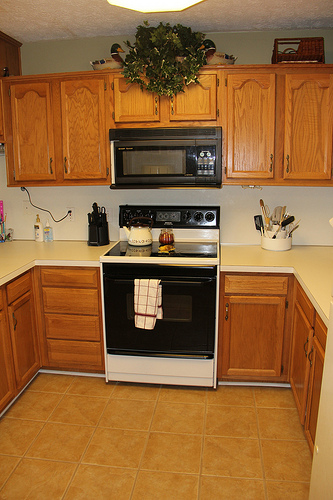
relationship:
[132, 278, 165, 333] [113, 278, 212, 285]
towel on handle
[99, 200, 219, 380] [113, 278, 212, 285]
stove has handle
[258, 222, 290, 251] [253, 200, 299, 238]
holder holds utensils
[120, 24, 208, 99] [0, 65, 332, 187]
plant on cabinet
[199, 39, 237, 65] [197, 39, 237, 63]
statue of duck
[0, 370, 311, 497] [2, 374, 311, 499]
tile on floor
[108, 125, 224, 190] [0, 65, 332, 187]
microwave on cabinet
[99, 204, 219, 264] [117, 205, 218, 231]
stove has panel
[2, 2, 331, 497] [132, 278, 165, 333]
kitchen has towel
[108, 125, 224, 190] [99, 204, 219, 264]
microwave over stove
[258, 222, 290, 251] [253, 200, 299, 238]
holder has utensils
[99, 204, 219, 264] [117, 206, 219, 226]
stove has knobs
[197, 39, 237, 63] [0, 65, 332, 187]
duck on cabinet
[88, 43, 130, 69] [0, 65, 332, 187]
duck on cabinet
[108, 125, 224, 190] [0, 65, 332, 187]
microwave under cabinet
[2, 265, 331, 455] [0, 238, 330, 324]
cabinet under counter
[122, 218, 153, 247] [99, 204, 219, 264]
tea pot on stove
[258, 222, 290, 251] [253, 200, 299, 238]
holder of utensils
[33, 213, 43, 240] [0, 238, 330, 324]
bottle on counter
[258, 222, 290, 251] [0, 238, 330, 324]
holder on counter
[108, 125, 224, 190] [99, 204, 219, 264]
microwave above stove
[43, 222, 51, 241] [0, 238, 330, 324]
bottle on counter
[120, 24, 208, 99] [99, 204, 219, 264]
plant above stove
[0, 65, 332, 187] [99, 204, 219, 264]
cabinet above stove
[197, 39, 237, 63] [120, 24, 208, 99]
duck next to plant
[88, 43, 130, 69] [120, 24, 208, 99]
duck next to plant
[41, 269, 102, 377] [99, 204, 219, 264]
drawers next to stove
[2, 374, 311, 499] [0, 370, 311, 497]
floor has tile